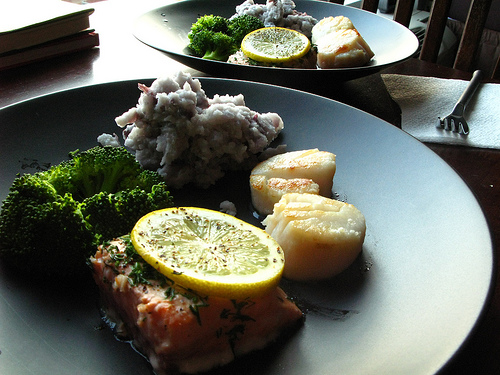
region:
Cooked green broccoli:
[0, 150, 158, 264]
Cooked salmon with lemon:
[86, 203, 306, 371]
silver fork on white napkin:
[420, 50, 495, 161]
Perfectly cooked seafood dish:
[0, 62, 495, 367]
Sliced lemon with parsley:
[116, 191, 291, 296]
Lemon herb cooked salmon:
[77, 205, 317, 362]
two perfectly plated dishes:
[76, 0, 411, 370]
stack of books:
[0, 0, 116, 65]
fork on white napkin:
[415, 60, 496, 148]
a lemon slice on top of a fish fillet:
[138, 194, 272, 293]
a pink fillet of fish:
[90, 229, 304, 372]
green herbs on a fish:
[93, 229, 207, 310]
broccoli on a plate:
[8, 147, 177, 261]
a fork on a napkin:
[436, 59, 487, 134]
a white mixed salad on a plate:
[122, 75, 289, 170]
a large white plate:
[1, 75, 490, 373]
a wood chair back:
[325, 1, 498, 66]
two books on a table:
[0, 6, 110, 63]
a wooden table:
[1, 1, 498, 373]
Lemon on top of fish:
[130, 208, 288, 294]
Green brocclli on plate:
[3, 142, 132, 239]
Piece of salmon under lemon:
[98, 286, 183, 361]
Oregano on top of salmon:
[108, 244, 145, 279]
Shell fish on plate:
[271, 196, 370, 268]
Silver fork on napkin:
[435, 64, 490, 139]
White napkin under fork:
[410, 77, 436, 127]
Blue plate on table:
[370, 137, 465, 312]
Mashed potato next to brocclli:
[123, 70, 256, 148]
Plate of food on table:
[1, 74, 496, 371]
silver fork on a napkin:
[436, 63, 481, 138]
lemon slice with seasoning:
[127, 205, 282, 300]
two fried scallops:
[250, 147, 365, 277]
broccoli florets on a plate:
[21, 140, 161, 270]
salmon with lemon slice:
[81, 200, 301, 370]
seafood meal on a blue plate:
[0, 75, 490, 370]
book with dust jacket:
[0, 0, 90, 50]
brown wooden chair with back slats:
[415, 0, 495, 70]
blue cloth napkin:
[380, 66, 495, 151]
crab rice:
[108, 69, 289, 181]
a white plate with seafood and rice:
[1, 82, 472, 362]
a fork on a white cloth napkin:
[430, 62, 486, 144]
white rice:
[122, 70, 262, 165]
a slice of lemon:
[136, 216, 273, 278]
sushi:
[101, 256, 297, 367]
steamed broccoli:
[8, 146, 150, 229]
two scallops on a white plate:
[252, 146, 362, 259]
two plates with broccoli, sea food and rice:
[11, 0, 477, 366]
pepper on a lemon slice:
[153, 208, 233, 274]